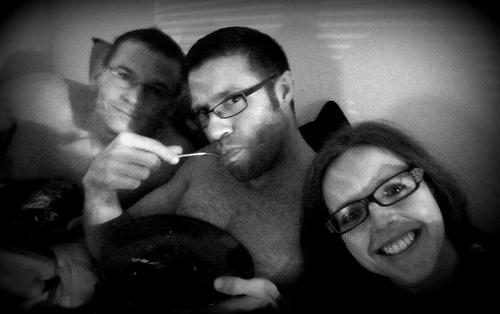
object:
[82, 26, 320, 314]
man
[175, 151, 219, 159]
spoon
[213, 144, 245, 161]
mouth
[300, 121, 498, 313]
woman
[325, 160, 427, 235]
glasses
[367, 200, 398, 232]
nose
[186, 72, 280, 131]
glasses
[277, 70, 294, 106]
left ear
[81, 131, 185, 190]
right hand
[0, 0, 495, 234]
wall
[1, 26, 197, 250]
man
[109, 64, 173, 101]
glasses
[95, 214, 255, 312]
plate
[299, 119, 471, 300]
hair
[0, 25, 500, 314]
people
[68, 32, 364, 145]
pillow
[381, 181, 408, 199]
eyes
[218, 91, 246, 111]
eyes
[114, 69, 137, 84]
eyes